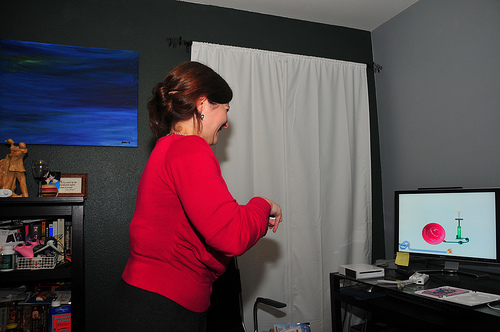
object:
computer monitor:
[394, 187, 500, 278]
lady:
[117, 61, 282, 332]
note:
[395, 252, 410, 267]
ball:
[422, 222, 445, 244]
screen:
[398, 191, 498, 260]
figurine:
[0, 139, 30, 198]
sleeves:
[167, 136, 272, 257]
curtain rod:
[184, 39, 387, 72]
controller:
[268, 214, 276, 227]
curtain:
[189, 40, 371, 331]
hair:
[147, 61, 234, 140]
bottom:
[111, 283, 214, 324]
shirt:
[121, 134, 269, 313]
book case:
[0, 196, 86, 332]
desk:
[328, 264, 500, 332]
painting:
[0, 40, 140, 147]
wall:
[386, 34, 500, 159]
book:
[414, 286, 500, 307]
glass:
[31, 159, 49, 197]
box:
[17, 255, 57, 270]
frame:
[58, 173, 87, 199]